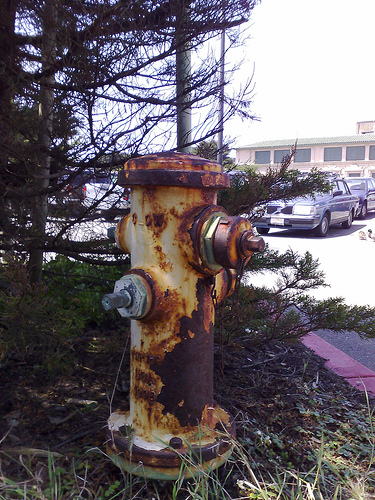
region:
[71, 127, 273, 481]
a rusted fire hydrant.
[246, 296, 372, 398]
a red curb.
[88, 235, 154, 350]
a valve on a rusted fire hydrant.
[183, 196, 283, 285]
a large valve on a fire hydrant.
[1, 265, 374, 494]
green grass on a curb.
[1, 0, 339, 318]
a tall pine tree in a parking lot.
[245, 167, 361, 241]
a car parked in a parking lot.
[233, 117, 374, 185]
a multi story building.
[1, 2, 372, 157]
a hazy gray sky.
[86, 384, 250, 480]
the bottom of a fire hydrant.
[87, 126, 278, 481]
This object is old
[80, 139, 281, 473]
This is a fire hydrant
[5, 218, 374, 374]
Branches are low to the ground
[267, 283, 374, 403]
Red is the color of the bricks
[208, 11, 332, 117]
It is sunny outside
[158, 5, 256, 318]
These are light poles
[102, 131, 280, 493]
Rust is over the fire hydrant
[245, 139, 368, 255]
Cars parked outside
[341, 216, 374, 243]
Ducks are walking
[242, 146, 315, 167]
This building has three windows together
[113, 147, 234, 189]
Top cover a fire hydrant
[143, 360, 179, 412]
Paint peeling from a fire hydrant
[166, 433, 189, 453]
Bolts to secure a fire hydrant to pipe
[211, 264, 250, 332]
Retaining chain on fire hydrant cover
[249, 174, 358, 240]
Car parked in the parking lot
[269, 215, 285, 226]
Front license plate on a car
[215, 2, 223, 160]
Utility pole for outdoor lighting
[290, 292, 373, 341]
Branches of an evergreen tree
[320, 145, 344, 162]
Window on the side of the building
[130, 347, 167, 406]
Letters molded into a fire hydrant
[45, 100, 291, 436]
an old fire hydrant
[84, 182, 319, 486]
a rusted fire hydrant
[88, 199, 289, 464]
an old rusted fire hydrant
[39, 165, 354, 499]
an old rusted hydrant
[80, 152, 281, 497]
a fire hydrant in the ground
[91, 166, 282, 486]
a hydrant in the ground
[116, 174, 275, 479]
an old hydrant in the ground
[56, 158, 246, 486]
a rusted hydrant in the ground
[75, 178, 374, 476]
a hydrant on the side of the road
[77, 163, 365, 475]
an old hydrant on the side of the road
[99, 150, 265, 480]
a fire hydrant is in the grass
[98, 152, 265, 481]
the hydrant has much rust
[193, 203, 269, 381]
the hydrant has a chain hanging from a plug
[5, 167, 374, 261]
cars are in the parking lot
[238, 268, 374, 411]
the curb is red by the hydrant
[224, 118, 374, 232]
a building is on the parking lot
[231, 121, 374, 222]
the building is pink in the background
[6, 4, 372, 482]
trees are behind the hydrants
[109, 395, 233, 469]
the bolts are rusted on the hydrant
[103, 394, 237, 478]
the base plate of the hydrant is rusted